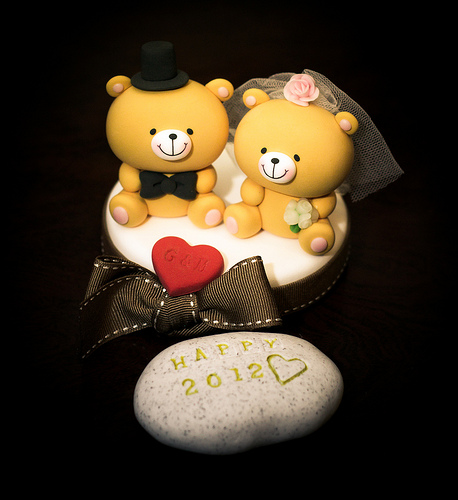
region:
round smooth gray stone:
[132, 327, 336, 456]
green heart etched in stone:
[268, 352, 305, 387]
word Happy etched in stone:
[167, 334, 283, 367]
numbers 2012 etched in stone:
[183, 360, 266, 401]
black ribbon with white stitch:
[70, 252, 276, 350]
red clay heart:
[153, 238, 215, 292]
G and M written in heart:
[162, 245, 206, 272]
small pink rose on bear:
[285, 71, 315, 105]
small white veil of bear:
[227, 68, 403, 199]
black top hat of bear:
[132, 43, 189, 92]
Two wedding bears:
[89, 61, 406, 257]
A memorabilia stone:
[137, 322, 349, 452]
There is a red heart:
[142, 233, 229, 295]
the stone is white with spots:
[133, 327, 380, 472]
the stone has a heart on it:
[137, 325, 362, 451]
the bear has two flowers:
[233, 73, 360, 253]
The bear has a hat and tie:
[94, 46, 228, 232]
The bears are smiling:
[91, 51, 361, 264]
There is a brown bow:
[74, 250, 278, 340]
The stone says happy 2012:
[133, 330, 346, 449]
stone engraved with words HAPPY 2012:
[128, 329, 347, 457]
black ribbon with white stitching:
[71, 252, 282, 335]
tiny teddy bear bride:
[221, 69, 404, 256]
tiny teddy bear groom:
[94, 38, 229, 231]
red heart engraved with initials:
[145, 229, 225, 300]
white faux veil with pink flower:
[222, 57, 403, 203]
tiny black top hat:
[126, 34, 190, 93]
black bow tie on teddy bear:
[136, 166, 196, 203]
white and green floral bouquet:
[281, 198, 320, 235]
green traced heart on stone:
[266, 352, 309, 386]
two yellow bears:
[100, 55, 379, 287]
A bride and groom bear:
[51, 41, 370, 259]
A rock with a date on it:
[95, 291, 351, 444]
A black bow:
[56, 199, 310, 375]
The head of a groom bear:
[91, 47, 241, 183]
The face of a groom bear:
[118, 102, 211, 166]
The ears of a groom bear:
[74, 36, 238, 114]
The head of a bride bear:
[234, 54, 369, 205]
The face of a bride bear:
[252, 130, 313, 187]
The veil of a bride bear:
[231, 61, 397, 189]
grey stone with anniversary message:
[132, 330, 351, 457]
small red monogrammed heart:
[150, 237, 223, 300]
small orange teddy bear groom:
[106, 74, 232, 229]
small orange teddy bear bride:
[225, 72, 359, 246]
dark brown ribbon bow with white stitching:
[85, 254, 268, 331]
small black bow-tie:
[140, 171, 198, 201]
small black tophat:
[124, 44, 198, 92]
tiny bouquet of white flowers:
[283, 198, 315, 231]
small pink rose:
[283, 73, 317, 108]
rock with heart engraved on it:
[130, 328, 345, 452]